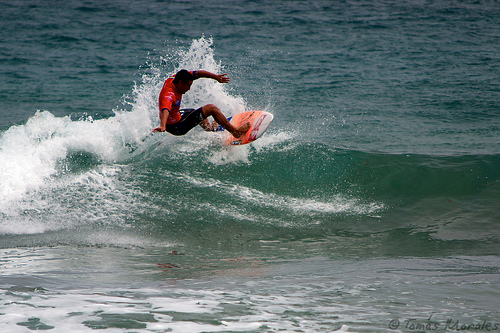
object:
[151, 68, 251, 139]
man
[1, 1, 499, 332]
ocean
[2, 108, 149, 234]
foam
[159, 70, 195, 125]
shirt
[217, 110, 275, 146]
surfboard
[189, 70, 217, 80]
arm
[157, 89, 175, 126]
arm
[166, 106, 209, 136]
shorts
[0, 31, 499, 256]
wave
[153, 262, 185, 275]
seaweed